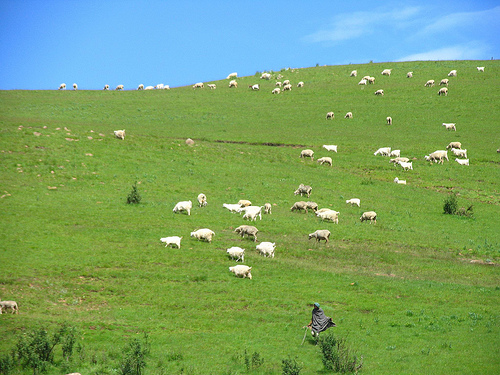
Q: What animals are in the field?
A: Sheep.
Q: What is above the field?
A: Sky.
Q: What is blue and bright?
A: The sky.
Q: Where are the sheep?
A: In the field.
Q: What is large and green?
A: The field.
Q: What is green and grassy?
A: The field.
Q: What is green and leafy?
A: The trees.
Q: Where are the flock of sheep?
A: In a field.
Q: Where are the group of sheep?
A: Resting in the field.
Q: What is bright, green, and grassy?
A: The field.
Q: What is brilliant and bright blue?
A: The sky.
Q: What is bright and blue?
A: The sky.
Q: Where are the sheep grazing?
A: On the hill.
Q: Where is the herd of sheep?
A: On the hill.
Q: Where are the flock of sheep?
A: In a grass field.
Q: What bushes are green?
A: The bushes near the bottom of the photo.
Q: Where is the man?
A: With the sheep.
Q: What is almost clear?
A: The sky.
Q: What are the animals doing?
A: Grazing.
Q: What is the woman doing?
A: Walking.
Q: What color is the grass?
A: Green.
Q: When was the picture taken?
A: During the day.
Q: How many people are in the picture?
A: One.